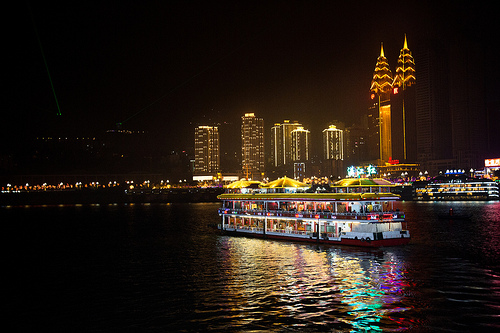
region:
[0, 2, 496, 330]
the scene takes place outdoors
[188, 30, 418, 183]
the buildings are lit up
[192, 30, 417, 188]
the buildings are tall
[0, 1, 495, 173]
the sky is dark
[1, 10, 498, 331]
it is night time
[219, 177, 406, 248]
the boat is on the water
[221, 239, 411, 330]
the water has a reflection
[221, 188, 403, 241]
people are on the boat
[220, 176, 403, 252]
the boat is lit up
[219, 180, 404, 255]
the boat is large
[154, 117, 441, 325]
Boat on the water.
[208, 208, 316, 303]
Light on the water.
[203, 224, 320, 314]
Lights reflected on the water.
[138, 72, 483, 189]
Buildings in the background.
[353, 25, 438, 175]
Tall buildings with lights.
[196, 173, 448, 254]
People on the boats.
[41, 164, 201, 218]
Lights on the dock.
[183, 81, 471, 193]
Shorter buildings in the background.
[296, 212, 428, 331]
Colorful lights on the water.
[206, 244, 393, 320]
Ripples in the waves.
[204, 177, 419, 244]
boat on water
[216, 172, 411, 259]
boat with neon lights in water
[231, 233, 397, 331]
neon lights reflecting off water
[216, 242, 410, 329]
reflection of neon lights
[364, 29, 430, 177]
building surrounded by light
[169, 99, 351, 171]
lit buildings across the bay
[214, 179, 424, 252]
party boat floating down river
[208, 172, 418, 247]
passengers on boat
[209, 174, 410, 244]
multi-colored lights on boat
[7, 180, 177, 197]
lights in the distance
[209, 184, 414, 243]
a tourist boat in the ocean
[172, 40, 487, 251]
tourist boat in front a city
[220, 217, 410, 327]
reflection of tourist boat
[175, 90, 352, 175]
big buildings in a city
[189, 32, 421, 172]
two skyscraper near tall buildings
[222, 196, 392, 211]
people inside tourist boat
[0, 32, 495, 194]
lights in a city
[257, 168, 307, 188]
a yellow umbrella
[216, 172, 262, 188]
a yellow umbrella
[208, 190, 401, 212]
roof of boat is yellow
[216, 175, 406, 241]
a cruise ship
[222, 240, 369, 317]
a reflection of light on the water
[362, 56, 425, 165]
a tall building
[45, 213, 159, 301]
the water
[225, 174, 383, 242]
lights on the cruise ship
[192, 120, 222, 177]
a building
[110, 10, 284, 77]
the sky is dark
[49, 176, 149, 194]
lights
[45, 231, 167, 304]
the water is dark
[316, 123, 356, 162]
a building